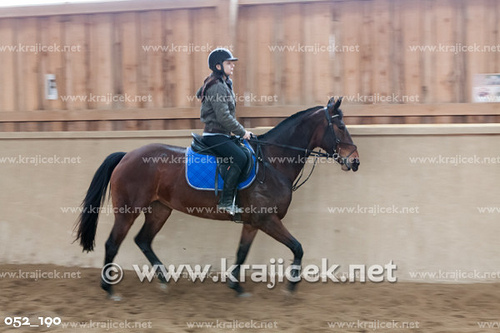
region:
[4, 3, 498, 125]
beams on wood fence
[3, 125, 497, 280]
surface of cement wall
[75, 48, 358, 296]
rider on top of horse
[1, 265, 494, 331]
dirt on ground surface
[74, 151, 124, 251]
flowing black horse tail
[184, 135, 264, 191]
blue pad under saddle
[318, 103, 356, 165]
bridle on horse head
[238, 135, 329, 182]
horse reign in hand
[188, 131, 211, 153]
back of leather saddle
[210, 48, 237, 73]
black helmet on head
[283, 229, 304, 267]
part of a horse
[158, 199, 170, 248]
part of a tail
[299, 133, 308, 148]
part of a neck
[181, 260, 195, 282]
edge of a wall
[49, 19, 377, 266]
person on the horse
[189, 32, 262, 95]
head of the person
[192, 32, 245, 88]
helmet on person's head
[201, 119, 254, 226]
leg of the person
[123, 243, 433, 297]
website on the photo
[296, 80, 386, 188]
head of the horse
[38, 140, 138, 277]
tail of the horse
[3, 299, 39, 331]
number in bottom right corner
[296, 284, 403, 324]
brown dirt on ground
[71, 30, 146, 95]
brown wall in photo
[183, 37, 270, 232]
woman wearing a hat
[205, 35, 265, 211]
woman wearing black pants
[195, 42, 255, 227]
woman wearing black boots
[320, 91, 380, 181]
face of a horse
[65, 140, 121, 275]
tail on a horse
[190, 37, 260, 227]
woman ridding a horse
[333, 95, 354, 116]
ear of a horse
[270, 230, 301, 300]
leg of a horse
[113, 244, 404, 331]
the website is www.krajicek.net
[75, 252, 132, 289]
a copyright symbol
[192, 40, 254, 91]
the woman is wearing a helmet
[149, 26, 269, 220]
the woman is wearing a gray jacket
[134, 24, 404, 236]
the woman is riding a horse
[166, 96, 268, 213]
she is sitting on a blue seat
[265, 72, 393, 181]
the horses head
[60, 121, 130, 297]
the horses tail and leg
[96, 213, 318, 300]
the horses legs are black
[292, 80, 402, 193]
the horse is wearing a harness